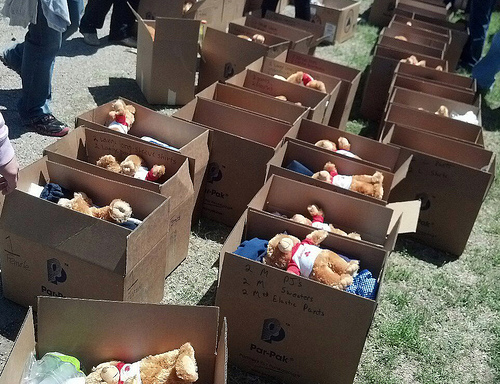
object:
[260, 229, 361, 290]
teddy bear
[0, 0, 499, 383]
grass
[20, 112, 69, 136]
shoe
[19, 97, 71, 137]
foot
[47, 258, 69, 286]
symbol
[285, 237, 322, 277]
shirt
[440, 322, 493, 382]
patches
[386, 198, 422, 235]
flap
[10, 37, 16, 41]
gravel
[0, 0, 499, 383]
ground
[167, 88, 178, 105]
tape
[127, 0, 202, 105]
box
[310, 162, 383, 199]
teddy bear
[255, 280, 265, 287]
handwriting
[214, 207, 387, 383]
boxes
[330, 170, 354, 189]
shirt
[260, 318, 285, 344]
logo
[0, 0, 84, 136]
person